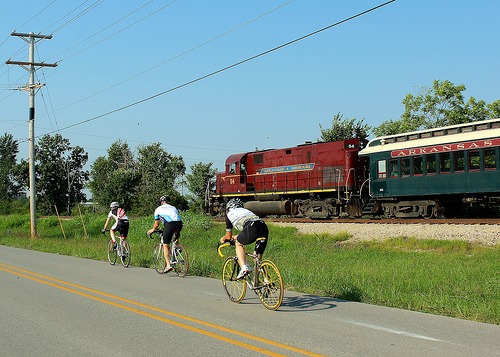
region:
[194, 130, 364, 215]
a red train engine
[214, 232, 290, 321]
bike with bright yellow accents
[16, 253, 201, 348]
two yellow lines in the road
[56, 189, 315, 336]
a few bicyclists on the road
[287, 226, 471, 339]
patch of grass by the road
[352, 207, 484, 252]
some gravel by the train tracks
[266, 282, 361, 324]
a shadow on the pavement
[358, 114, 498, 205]
a green and white train car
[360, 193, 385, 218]
a few metal stairs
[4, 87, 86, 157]
a few crossed power lines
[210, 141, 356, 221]
a dark red train engine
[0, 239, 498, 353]
a paved two way street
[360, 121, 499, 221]
a green train passenger car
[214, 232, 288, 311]
a yellow bicycle on street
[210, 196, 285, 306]
a man riding a bicycle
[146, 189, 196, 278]
a man riding a bicycle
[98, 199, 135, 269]
a man riding a bicycle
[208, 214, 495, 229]
a set of train tracks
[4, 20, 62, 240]
a tall telephone pole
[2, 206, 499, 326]
a patch of green grass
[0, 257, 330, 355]
THE YELLOW LINES ARE PAINTED ON THE ROAD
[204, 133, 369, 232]
THE ENGINE IS RED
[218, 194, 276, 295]
THE WOMAN IS WEARING BLACK SHORTS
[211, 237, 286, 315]
THE BIKE IS YELLOW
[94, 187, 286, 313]
THE RIDERS ARE ON THE ROAD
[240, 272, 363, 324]
THE SHADOW IS ON THE GROUND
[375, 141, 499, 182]
THE TRAIN HAS LOTS OF WINDOWS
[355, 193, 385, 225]
THESE ARE STEPS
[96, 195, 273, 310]
THE RIDERS ARE WEARING HELMETS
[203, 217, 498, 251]
THE GRAVEL IS BESIDE THE TRACKS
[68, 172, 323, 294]
three people riding bikes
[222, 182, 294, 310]
a person riding a yellow bike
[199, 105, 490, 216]
a train on train tracks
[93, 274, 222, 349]
yellow lines painted on a road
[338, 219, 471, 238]
gravel by train tracks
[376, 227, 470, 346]
a patch of grass next to a road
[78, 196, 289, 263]
three people wearing black shorts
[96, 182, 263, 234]
three people wearing helmets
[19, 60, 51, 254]
a wood electrical pole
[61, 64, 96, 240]
two guide wires connected to a pole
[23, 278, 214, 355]
double yellow line in the middle of the road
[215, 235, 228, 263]
handle bar on bike is yellow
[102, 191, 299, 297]
three bike riders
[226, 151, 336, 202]
engine car is red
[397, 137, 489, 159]
ARKANSAS is written on the train car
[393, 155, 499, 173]
windows on the train car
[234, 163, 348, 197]
black railing along the train car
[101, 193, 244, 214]
riders wearing safety helmets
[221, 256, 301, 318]
bike rims are yellow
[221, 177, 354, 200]
yellow stripe along bottom of railing